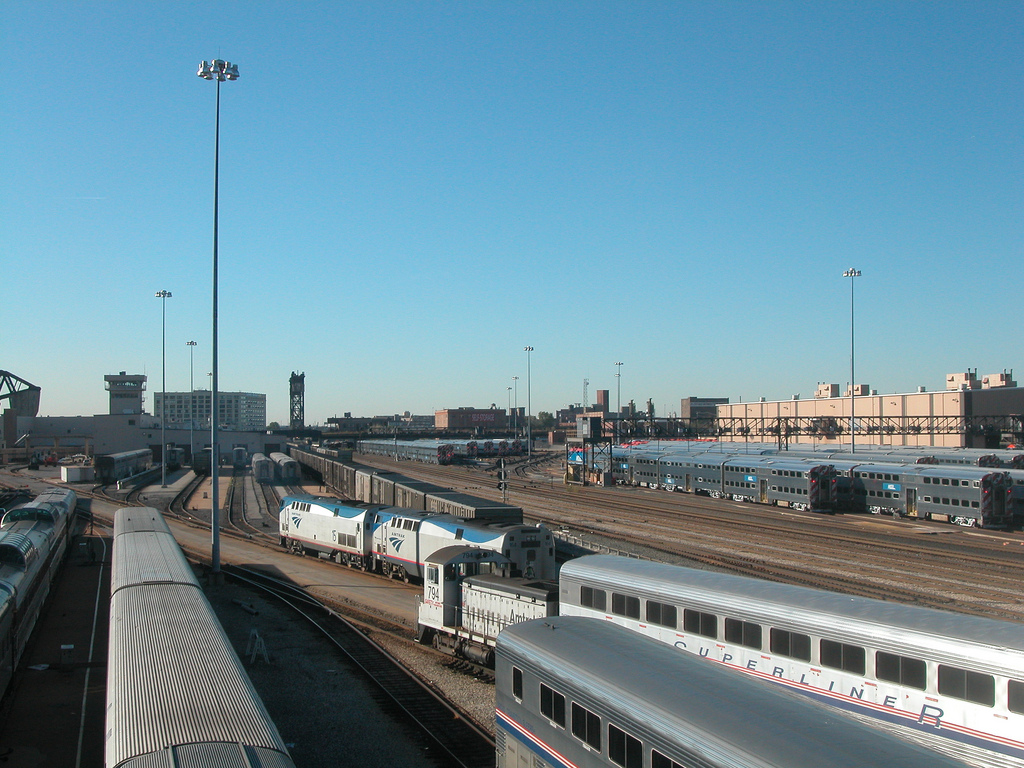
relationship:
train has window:
[562, 549, 1021, 763] [600, 571, 648, 626]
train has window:
[562, 549, 1021, 763] [676, 597, 750, 652]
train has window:
[562, 549, 1021, 763] [799, 625, 888, 697]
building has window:
[151, 388, 266, 432] [172, 402, 216, 429]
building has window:
[151, 388, 266, 432] [216, 396, 253, 429]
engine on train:
[402, 541, 614, 691] [427, 519, 1007, 697]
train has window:
[493, 616, 965, 764] [510, 662, 524, 702]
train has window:
[493, 616, 965, 764] [534, 679, 571, 732]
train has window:
[493, 616, 965, 764] [569, 698, 602, 750]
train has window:
[493, 616, 965, 764] [608, 726, 645, 765]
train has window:
[493, 616, 965, 764] [644, 744, 681, 764]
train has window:
[493, 616, 965, 764] [510, 666, 528, 703]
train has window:
[493, 616, 965, 764] [539, 685, 566, 733]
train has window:
[493, 616, 965, 764] [567, 703, 600, 751]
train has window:
[493, 616, 965, 764] [605, 718, 645, 764]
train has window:
[562, 549, 1021, 763] [580, 582, 604, 609]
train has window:
[562, 549, 1021, 763] [608, 588, 641, 621]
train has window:
[562, 549, 1021, 763] [644, 601, 679, 632]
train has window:
[562, 549, 1021, 763] [685, 606, 718, 645]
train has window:
[562, 549, 1021, 763] [720, 616, 760, 653]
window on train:
[610, 586, 645, 623] [552, 544, 1019, 740]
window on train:
[639, 587, 688, 627] [562, 549, 1021, 763]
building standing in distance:
[152, 387, 267, 431] [3, 286, 991, 470]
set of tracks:
[137, 467, 241, 509] [132, 465, 247, 507]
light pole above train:
[177, 50, 258, 563] [96, 506, 311, 764]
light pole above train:
[177, 50, 258, 563] [0, 467, 94, 666]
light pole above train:
[160, 285, 169, 490] [97, 436, 160, 497]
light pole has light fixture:
[209, 43, 223, 574] [192, 52, 250, 92]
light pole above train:
[209, 43, 223, 574] [102, 498, 301, 764]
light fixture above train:
[192, 52, 250, 92] [102, 498, 301, 764]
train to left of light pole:
[102, 498, 301, 764] [209, 43, 223, 574]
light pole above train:
[145, 276, 182, 495] [82, 436, 152, 497]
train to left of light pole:
[82, 436, 152, 497] [145, 276, 182, 495]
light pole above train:
[209, 43, 223, 574] [99, 503, 300, 767]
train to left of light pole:
[99, 503, 300, 767] [209, 43, 223, 574]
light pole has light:
[209, 43, 223, 574] [177, 52, 257, 94]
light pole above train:
[209, 43, 223, 574] [93, 488, 295, 765]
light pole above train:
[160, 285, 169, 490] [95, 440, 152, 492]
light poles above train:
[495, 251, 885, 459] [564, 444, 845, 515]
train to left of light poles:
[564, 444, 845, 515] [495, 251, 885, 459]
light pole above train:
[827, 257, 877, 445] [564, 444, 845, 515]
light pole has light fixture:
[849, 265, 858, 456] [833, 258, 872, 284]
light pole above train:
[849, 265, 858, 456] [601, 438, 856, 514]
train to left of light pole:
[601, 438, 856, 514] [849, 265, 858, 456]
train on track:
[488, 612, 978, 766] [227, 566, 491, 759]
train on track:
[411, 541, 1023, 766] [179, 557, 495, 678]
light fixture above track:
[192, 52, 251, 92] [180, 547, 496, 768]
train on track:
[261, 482, 557, 591] [164, 475, 417, 581]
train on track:
[99, 503, 300, 767] [73, 467, 296, 764]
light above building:
[171, 328, 219, 469] [149, 386, 256, 445]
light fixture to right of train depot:
[834, 257, 874, 452] [6, 428, 1011, 764]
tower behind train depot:
[283, 365, 310, 446] [6, 428, 1011, 764]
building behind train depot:
[151, 388, 266, 432] [6, 428, 1011, 764]